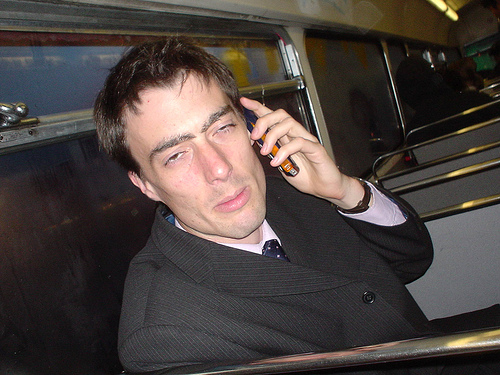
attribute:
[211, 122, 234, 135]
eye — squinty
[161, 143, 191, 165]
eye — squinty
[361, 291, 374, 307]
button — black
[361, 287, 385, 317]
button — BLACK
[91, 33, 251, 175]
hair — short, brown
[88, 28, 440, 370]
man — talking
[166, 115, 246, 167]
eyes — barely open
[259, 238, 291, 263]
tie — dark blue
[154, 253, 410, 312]
jacket — black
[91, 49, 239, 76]
hair — brown